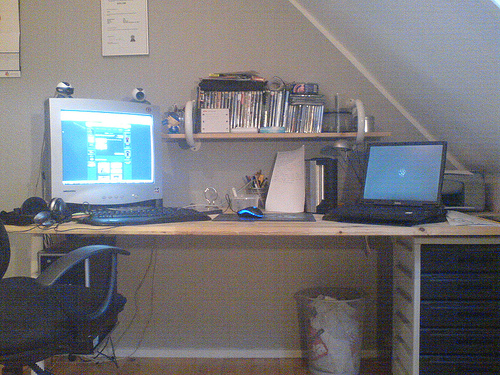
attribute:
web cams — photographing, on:
[58, 83, 154, 102]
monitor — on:
[46, 101, 166, 204]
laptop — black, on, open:
[321, 138, 448, 222]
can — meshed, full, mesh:
[293, 283, 370, 375]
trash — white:
[309, 307, 351, 365]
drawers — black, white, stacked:
[392, 224, 498, 372]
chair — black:
[3, 217, 127, 373]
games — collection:
[194, 91, 323, 132]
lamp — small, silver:
[330, 121, 372, 158]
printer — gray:
[443, 169, 490, 211]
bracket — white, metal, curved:
[184, 96, 200, 157]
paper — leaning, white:
[267, 147, 311, 213]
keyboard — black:
[77, 203, 213, 227]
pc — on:
[49, 73, 450, 232]